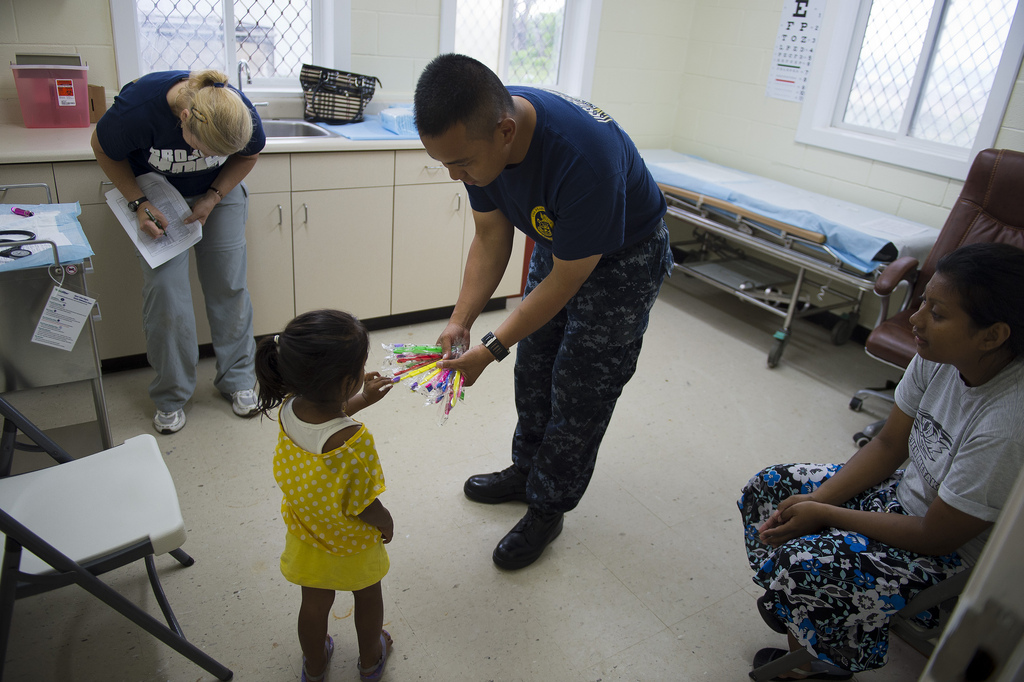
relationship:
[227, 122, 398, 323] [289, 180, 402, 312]
cabinet has a door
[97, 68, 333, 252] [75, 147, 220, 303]
woman bending with a paper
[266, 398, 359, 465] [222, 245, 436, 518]
undershirt on a girl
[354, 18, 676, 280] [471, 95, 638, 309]
man bending down in a shirt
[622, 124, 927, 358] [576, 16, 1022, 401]
bed up against wall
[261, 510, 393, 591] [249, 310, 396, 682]
skirt on a child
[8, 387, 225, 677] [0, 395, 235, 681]
chair with chair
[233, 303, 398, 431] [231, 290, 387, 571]
hair on child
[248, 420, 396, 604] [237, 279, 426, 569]
shirt on child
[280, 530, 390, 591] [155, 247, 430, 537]
skirt on child